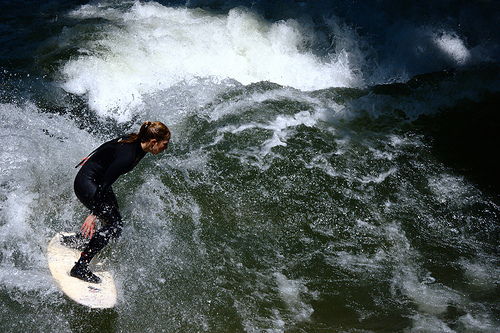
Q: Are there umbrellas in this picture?
A: No, there are no umbrellas.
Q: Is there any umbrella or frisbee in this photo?
A: No, there are no umbrellas or frisbees.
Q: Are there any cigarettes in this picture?
A: No, there are no cigarettes.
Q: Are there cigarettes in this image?
A: No, there are no cigarettes.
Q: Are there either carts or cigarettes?
A: No, there are no cigarettes or carts.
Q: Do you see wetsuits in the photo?
A: Yes, there is a wetsuit.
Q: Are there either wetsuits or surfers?
A: Yes, there is a wetsuit.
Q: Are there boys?
A: No, there are no boys.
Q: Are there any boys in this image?
A: No, there are no boys.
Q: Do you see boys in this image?
A: No, there are no boys.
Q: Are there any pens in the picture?
A: No, there are no pens.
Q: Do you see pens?
A: No, there are no pens.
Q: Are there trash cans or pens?
A: No, there are no pens or trash cans.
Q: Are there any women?
A: Yes, there is a woman.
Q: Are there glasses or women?
A: Yes, there is a woman.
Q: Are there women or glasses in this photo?
A: Yes, there is a woman.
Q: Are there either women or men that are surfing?
A: Yes, the woman is surfing.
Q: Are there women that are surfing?
A: Yes, there is a woman that is surfing.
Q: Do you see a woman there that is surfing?
A: Yes, there is a woman that is surfing.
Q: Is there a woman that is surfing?
A: Yes, there is a woman that is surfing.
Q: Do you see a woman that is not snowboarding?
A: Yes, there is a woman that is surfing .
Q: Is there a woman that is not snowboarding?
A: Yes, there is a woman that is surfing.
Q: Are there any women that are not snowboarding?
A: Yes, there is a woman that is surfing.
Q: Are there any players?
A: No, there are no players.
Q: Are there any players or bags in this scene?
A: No, there are no players or bags.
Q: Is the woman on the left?
A: Yes, the woman is on the left of the image.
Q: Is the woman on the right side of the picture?
A: No, the woman is on the left of the image.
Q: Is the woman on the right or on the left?
A: The woman is on the left of the image.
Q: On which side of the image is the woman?
A: The woman is on the left of the image.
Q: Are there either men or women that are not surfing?
A: No, there is a woman but she is surfing.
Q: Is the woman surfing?
A: Yes, the woman is surfing.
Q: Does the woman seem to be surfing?
A: Yes, the woman is surfing.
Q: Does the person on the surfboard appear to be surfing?
A: Yes, the woman is surfing.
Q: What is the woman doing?
A: The woman is surfing.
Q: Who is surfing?
A: The woman is surfing.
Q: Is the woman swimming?
A: No, the woman is surfing.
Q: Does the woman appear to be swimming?
A: No, the woman is surfing.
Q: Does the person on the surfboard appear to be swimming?
A: No, the woman is surfing.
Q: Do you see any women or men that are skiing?
A: No, there is a woman but she is surfing.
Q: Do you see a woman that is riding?
A: No, there is a woman but she is surfing.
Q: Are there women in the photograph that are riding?
A: No, there is a woman but she is surfing.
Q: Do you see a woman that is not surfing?
A: No, there is a woman but she is surfing.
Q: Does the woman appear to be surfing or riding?
A: The woman is surfing.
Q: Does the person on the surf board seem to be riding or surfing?
A: The woman is surfing.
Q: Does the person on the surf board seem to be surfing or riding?
A: The woman is surfing.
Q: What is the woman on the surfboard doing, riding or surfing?
A: The woman is surfing.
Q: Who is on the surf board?
A: The woman is on the surf board.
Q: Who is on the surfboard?
A: The woman is on the surf board.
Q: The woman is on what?
A: The woman is on the surfboard.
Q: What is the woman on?
A: The woman is on the surfboard.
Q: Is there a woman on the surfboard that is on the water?
A: Yes, there is a woman on the surfboard.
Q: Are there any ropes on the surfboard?
A: No, there is a woman on the surfboard.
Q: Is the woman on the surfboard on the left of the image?
A: Yes, the woman is on the surfboard.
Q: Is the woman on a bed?
A: No, the woman is on the surfboard.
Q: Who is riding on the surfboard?
A: The woman is riding on the surfboard.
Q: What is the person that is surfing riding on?
A: The woman is riding on the surf board.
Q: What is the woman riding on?
A: The woman is riding on the surf board.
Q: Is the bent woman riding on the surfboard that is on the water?
A: Yes, the woman is riding on the surfboard.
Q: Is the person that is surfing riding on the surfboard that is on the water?
A: Yes, the woman is riding on the surfboard.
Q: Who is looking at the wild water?
A: The woman is looking at the water.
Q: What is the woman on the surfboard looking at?
A: The woman is looking at the water.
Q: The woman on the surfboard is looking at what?
A: The woman is looking at the water.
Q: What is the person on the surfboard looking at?
A: The woman is looking at the water.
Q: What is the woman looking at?
A: The woman is looking at the water.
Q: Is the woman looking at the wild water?
A: Yes, the woman is looking at the water.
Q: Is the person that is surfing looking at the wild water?
A: Yes, the woman is looking at the water.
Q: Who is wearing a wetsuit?
A: The woman is wearing a wetsuit.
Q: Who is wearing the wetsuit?
A: The woman is wearing a wetsuit.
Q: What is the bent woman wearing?
A: The woman is wearing a wetsuit.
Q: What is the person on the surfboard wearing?
A: The woman is wearing a wetsuit.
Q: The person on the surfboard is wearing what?
A: The woman is wearing a wetsuit.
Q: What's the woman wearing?
A: The woman is wearing a wetsuit.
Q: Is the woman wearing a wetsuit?
A: Yes, the woman is wearing a wetsuit.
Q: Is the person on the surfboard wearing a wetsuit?
A: Yes, the woman is wearing a wetsuit.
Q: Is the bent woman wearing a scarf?
A: No, the woman is wearing a wetsuit.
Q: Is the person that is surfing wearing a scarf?
A: No, the woman is wearing a wetsuit.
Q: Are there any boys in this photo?
A: No, there are no boys.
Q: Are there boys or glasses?
A: No, there are no boys or glasses.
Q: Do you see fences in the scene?
A: No, there are no fences.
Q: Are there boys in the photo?
A: No, there are no boys.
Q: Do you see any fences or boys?
A: No, there are no boys or fences.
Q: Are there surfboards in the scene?
A: Yes, there is a surfboard.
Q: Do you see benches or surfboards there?
A: Yes, there is a surfboard.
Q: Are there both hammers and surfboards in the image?
A: No, there is a surfboard but no hammers.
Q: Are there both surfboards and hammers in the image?
A: No, there is a surfboard but no hammers.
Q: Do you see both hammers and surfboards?
A: No, there is a surfboard but no hammers.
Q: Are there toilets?
A: No, there are no toilets.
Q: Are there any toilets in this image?
A: No, there are no toilets.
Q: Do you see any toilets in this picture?
A: No, there are no toilets.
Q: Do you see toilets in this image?
A: No, there are no toilets.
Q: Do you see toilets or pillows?
A: No, there are no toilets or pillows.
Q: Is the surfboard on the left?
A: Yes, the surfboard is on the left of the image.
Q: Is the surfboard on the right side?
A: No, the surfboard is on the left of the image.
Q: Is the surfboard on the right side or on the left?
A: The surfboard is on the left of the image.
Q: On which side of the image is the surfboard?
A: The surfboard is on the left of the image.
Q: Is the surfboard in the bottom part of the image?
A: Yes, the surfboard is in the bottom of the image.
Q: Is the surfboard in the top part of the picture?
A: No, the surfboard is in the bottom of the image.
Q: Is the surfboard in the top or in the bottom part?
A: The surfboard is in the bottom of the image.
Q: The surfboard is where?
A: The surfboard is on the water.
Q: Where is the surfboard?
A: The surfboard is on the water.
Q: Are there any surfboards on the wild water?
A: Yes, there is a surfboard on the water.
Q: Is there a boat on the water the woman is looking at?
A: No, there is a surfboard on the water.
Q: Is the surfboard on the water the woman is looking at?
A: Yes, the surfboard is on the water.